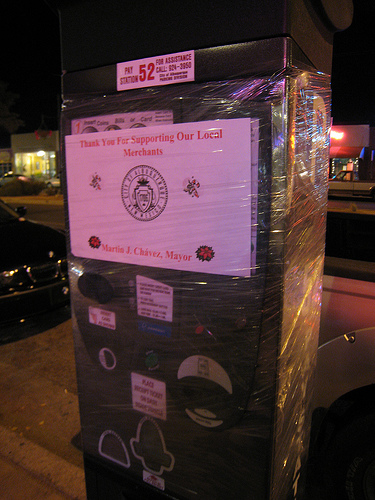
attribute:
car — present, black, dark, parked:
[0, 184, 71, 336]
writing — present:
[75, 128, 239, 158]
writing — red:
[114, 55, 200, 87]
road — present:
[0, 195, 373, 290]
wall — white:
[11, 125, 369, 193]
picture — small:
[121, 163, 167, 223]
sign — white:
[62, 119, 261, 279]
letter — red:
[117, 52, 194, 87]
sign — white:
[114, 50, 196, 92]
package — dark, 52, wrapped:
[56, 3, 333, 498]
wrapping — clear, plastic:
[57, 72, 334, 499]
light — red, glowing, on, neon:
[328, 126, 348, 147]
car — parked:
[0, 168, 55, 200]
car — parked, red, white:
[324, 168, 374, 201]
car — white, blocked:
[43, 172, 68, 192]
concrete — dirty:
[0, 337, 84, 498]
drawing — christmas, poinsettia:
[190, 243, 215, 264]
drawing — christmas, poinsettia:
[87, 235, 107, 251]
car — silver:
[300, 261, 374, 499]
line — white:
[21, 215, 69, 234]